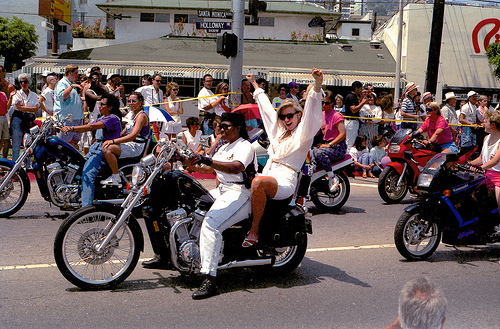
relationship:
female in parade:
[234, 68, 323, 247] [2, 3, 495, 324]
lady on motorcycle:
[234, 68, 323, 247] [53, 140, 309, 293]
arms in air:
[235, 68, 334, 136] [21, 7, 213, 58]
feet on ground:
[179, 266, 231, 301] [14, 173, 490, 323]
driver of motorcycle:
[188, 107, 259, 305] [53, 140, 309, 293]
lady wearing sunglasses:
[411, 98, 461, 159] [420, 98, 443, 119]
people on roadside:
[3, 58, 495, 124] [5, 0, 499, 167]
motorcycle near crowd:
[372, 125, 481, 203] [3, 58, 495, 124]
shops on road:
[16, 2, 498, 77] [14, 173, 490, 323]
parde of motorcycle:
[2, 3, 495, 324] [53, 138, 314, 290]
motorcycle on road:
[53, 138, 314, 290] [14, 173, 490, 323]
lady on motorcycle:
[78, 92, 126, 209] [0, 116, 179, 213]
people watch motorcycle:
[3, 58, 495, 124] [53, 138, 314, 290]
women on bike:
[62, 86, 158, 218] [0, 116, 179, 213]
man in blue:
[52, 62, 88, 144] [53, 77, 87, 126]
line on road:
[307, 244, 395, 252] [14, 173, 490, 323]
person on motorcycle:
[188, 107, 259, 305] [53, 140, 309, 293]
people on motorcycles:
[3, 58, 495, 124] [47, 91, 499, 177]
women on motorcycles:
[0, 91, 158, 215] [0, 116, 179, 213]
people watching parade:
[3, 58, 495, 124] [2, 3, 495, 324]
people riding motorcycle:
[47, 91, 499, 177] [53, 138, 314, 290]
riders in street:
[47, 91, 499, 177] [14, 173, 490, 323]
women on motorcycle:
[0, 91, 158, 215] [53, 138, 314, 290]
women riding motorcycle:
[62, 86, 158, 218] [53, 138, 314, 290]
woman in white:
[234, 68, 323, 247] [264, 126, 321, 191]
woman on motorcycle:
[411, 98, 461, 159] [372, 125, 481, 203]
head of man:
[2, 63, 15, 89] [1, 67, 16, 99]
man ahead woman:
[188, 107, 259, 305] [234, 68, 323, 247]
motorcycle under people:
[53, 140, 309, 293] [191, 67, 328, 301]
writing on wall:
[460, 14, 499, 58] [409, 6, 500, 89]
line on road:
[305, 241, 401, 250] [14, 173, 490, 323]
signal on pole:
[206, 28, 245, 58] [226, 2, 246, 114]